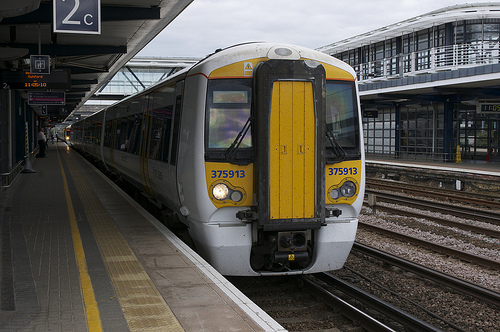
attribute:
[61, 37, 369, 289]
train — grey, yellow, long, white, black, large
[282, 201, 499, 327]
track — brown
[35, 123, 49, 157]
man — standing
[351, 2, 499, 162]
building — large, two story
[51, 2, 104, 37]
signs — white, black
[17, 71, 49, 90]
sign — lit, digital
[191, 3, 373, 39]
sky — overcast, white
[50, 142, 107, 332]
line — yellow, long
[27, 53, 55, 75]
sign — grey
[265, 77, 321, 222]
door — yellow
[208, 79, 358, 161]
windshields — black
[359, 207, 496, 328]
tracks — steel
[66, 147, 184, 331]
stripe — yellow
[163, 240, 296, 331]
stripe — white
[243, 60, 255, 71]
sign — yellow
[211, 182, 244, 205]
headlight — on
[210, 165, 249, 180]
numbers — blue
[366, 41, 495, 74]
railing — white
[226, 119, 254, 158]
wiper — black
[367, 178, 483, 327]
tracks — railroad tracks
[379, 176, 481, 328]
tracks — train tracks